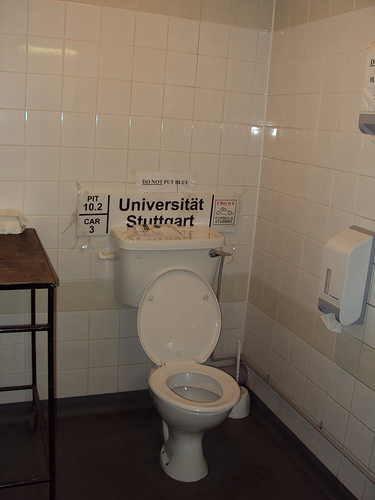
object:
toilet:
[136, 262, 241, 483]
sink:
[111, 222, 227, 252]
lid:
[136, 268, 224, 366]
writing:
[118, 192, 204, 230]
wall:
[0, 3, 375, 498]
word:
[118, 195, 131, 210]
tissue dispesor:
[317, 225, 373, 333]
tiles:
[314, 128, 337, 170]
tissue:
[319, 312, 344, 333]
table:
[0, 226, 60, 499]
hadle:
[208, 248, 231, 257]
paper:
[0, 210, 28, 235]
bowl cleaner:
[227, 385, 251, 421]